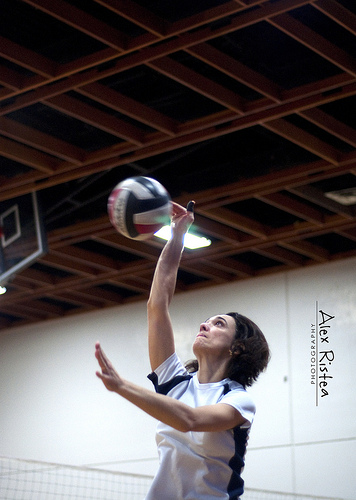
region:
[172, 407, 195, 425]
part of an elbow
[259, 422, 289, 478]
part of a line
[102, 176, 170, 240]
red, black, and white volley ball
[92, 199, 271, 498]
woman about to serve a volley ball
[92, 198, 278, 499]
woman about to hit a volleyball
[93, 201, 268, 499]
woman jumping up to hit the volleyball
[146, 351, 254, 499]
black and white shirt on the woman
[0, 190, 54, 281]
basketball goal on the ceiling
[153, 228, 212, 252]
light on the cieling of the building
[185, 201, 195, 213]
small black wrap on the woman's thumb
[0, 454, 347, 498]
white volleyball net behind the woman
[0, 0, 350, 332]
wooden beams over the woman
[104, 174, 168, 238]
A ball in the picture.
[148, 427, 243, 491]
A white and black jersey.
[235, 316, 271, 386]
Black hair in the picture.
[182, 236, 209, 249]
Rays of light on the roof.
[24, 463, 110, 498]
A volleyball net in the picture.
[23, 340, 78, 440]
A white wall in the photo.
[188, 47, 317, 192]
A wooden roof in the photo.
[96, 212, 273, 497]
A female volleyball player.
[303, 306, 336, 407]
Writings on the wall.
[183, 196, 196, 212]
A black bandage in the photo.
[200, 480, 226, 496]
part of a shirt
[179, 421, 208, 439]
part of an elbow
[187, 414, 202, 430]
part of an elbow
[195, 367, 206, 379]
neck of a woman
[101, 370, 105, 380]
finger of a lady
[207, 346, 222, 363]
mouth of a woman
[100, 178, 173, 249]
girl is serving volleyball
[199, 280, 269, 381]
girl has brown hair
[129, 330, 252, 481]
white and black shirt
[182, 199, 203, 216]
black athletic tape on thumb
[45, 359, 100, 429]
white wall behind girl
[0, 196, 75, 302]
folded in basketball backboard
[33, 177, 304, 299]
brown and wood ceiling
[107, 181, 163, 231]
black stripes on volleyball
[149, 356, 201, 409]
black stripe on shirt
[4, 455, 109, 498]
white tape on volleyball net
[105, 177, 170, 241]
red, black and white ball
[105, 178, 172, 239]
The volley ball the player is hitting.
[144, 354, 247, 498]
The shirt the player is wearing.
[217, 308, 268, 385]
The short hair of the player.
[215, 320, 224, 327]
The eye of the player.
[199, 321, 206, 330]
The nose of the player.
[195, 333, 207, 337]
The mouth of the player.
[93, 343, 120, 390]
The right hand of the player.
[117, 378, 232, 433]
The right arm of the player.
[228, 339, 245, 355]
The ear of the player.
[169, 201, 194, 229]
The left hand of the player.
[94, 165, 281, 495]
This is a person